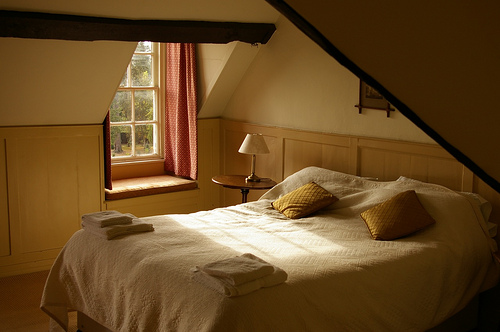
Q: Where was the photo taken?
A: Bedroom.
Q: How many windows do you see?
A: 1.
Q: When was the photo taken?
A: Daytime.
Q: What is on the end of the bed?
A: Towels.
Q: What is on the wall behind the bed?
A: A photo.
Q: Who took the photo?
A: The photographer.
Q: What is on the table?
A: A lamp.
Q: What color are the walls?
A: White and yellow.